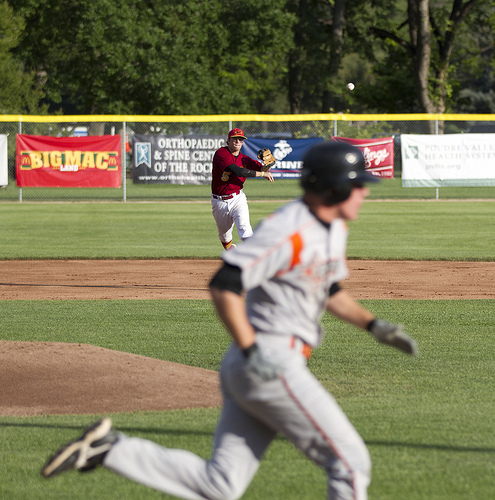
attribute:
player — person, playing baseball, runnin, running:
[47, 138, 422, 499]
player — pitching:
[210, 127, 280, 250]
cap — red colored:
[228, 127, 248, 141]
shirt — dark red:
[206, 148, 262, 192]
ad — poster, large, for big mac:
[17, 125, 124, 199]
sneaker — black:
[40, 419, 120, 475]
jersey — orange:
[224, 205, 351, 343]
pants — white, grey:
[108, 331, 381, 495]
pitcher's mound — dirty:
[9, 337, 215, 415]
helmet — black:
[298, 143, 384, 189]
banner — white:
[399, 127, 495, 187]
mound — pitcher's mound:
[5, 341, 224, 416]